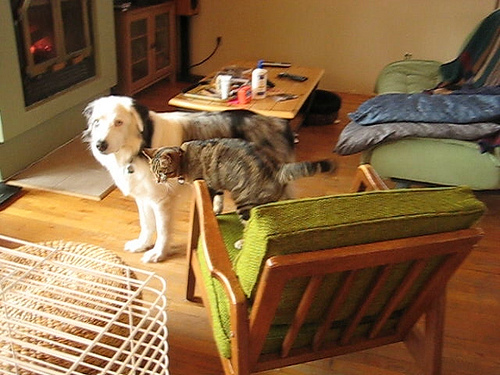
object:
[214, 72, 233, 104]
white cup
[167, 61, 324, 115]
table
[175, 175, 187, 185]
bell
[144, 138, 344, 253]
cat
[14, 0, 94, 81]
fireplace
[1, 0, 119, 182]
wall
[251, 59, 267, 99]
bottle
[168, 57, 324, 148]
table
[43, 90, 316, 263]
dog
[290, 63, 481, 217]
pillow